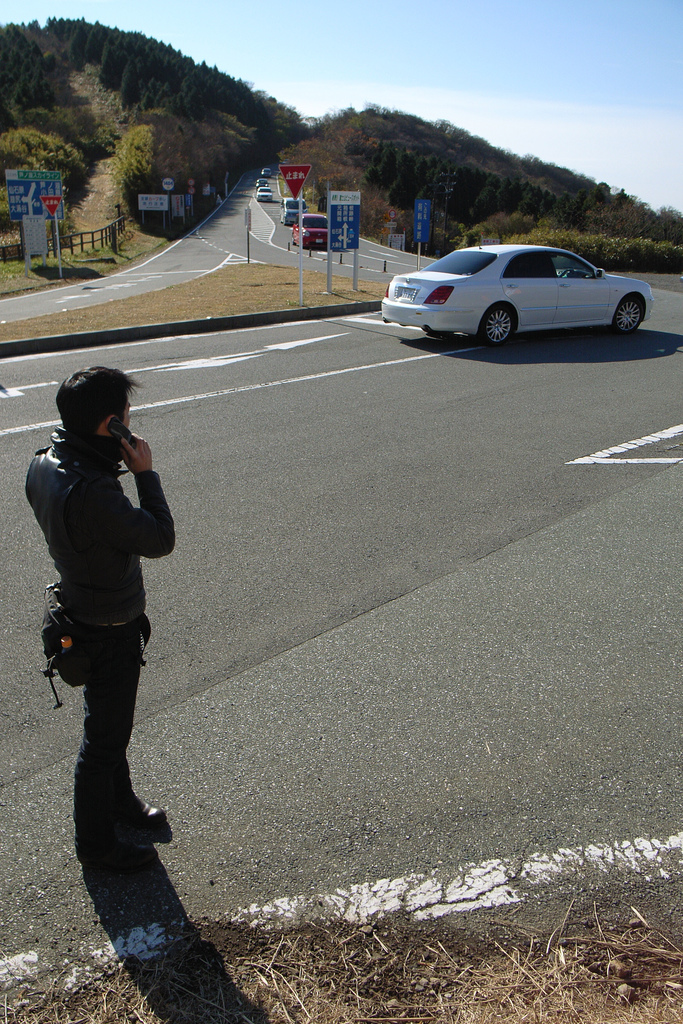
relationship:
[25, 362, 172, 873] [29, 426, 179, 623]
person wearing jacket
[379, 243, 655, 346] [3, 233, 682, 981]
car at intersection